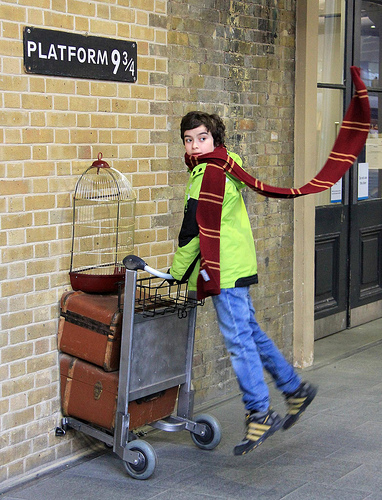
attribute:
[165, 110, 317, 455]
kid — looking, backwards, jumping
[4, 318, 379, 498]
ground — gray, asphalt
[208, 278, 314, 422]
jeans — blue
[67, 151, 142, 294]
cage — red, silver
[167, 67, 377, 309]
scarf — long, red, burgandy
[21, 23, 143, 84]
sign — black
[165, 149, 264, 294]
jacket — green, yellow, neon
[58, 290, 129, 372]
suitcase — brown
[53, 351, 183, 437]
suitcase — brown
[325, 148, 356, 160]
stripe — yellow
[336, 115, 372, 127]
stripe — yellow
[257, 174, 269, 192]
stripe — yellow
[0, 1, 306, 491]
wall — brick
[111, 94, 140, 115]
brick — brown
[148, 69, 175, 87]
brick — gray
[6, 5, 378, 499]
platform — 9 3/4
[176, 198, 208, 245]
accent — black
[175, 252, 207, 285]
accent — black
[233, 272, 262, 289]
accent — black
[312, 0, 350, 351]
door — double, black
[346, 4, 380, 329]
door — double, black